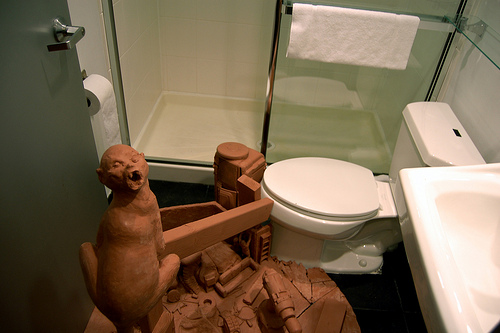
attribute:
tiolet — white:
[246, 88, 487, 318]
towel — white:
[280, 4, 423, 83]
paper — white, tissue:
[73, 66, 115, 126]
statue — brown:
[76, 128, 358, 330]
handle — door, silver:
[46, 14, 87, 55]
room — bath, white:
[2, 0, 496, 330]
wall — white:
[429, 6, 487, 330]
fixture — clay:
[54, 124, 373, 330]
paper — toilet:
[71, 68, 123, 134]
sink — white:
[378, 126, 498, 326]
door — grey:
[0, 6, 112, 330]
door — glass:
[261, 1, 469, 211]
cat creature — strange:
[76, 141, 183, 330]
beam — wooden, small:
[160, 195, 272, 259]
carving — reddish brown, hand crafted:
[74, 140, 359, 331]